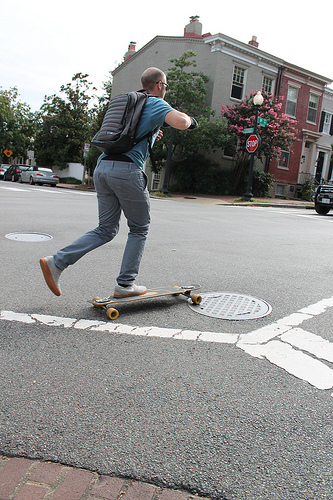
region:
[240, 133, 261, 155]
red octagonal stop sign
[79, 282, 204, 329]
old style skate board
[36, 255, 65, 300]
gum soled white shoes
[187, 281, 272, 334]
metal sewer system cover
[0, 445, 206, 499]
red bricks next to road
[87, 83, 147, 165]
grey striped back pack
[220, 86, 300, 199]
tall tree covered in pink flowers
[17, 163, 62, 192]
parked silver car with a black roof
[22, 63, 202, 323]
man riding a skateboard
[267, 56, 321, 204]
tall red brick building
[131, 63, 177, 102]
Man has thinning hair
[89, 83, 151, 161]
The man is carrying a backpack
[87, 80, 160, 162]
The man's backpack is gray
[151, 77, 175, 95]
The man is wearing glasses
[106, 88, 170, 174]
Man is wearing a blue shirt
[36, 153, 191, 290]
The man is wearing denim pants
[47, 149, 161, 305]
The man's pants are blue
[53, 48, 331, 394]
The man is not in the crosswalk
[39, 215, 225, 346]
The man is on a skateboard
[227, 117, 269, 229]
There is a stop sign at the intersection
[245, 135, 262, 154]
Red and white stop sign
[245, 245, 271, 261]
Small part of black street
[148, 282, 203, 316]
Half of the man's skateboard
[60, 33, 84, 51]
A white overcast sky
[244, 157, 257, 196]
Black pole that connects to stop sign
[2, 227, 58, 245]
Gray sewage hole in the street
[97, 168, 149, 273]
Gray jeans of the skateboarder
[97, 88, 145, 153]
Gray and black backpack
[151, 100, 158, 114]
Small part of green shirt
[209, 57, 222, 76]
Top part of gray building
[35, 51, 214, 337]
a man riding a skateboard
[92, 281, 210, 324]
a skateboard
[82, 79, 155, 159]
a grey backpack on the man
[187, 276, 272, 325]
a manhole cover in the road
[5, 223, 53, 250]
a manhole cover in the road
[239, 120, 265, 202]
a stop sign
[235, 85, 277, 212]
a street light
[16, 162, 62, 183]
a parked silver car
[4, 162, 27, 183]
a parked black car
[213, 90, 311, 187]
a tree with pink flowers on it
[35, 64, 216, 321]
Man on a skateboard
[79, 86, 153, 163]
A grey backpack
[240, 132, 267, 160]
A red stop sign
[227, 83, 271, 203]
A sign pole with a light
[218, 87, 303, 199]
A pink flowering tree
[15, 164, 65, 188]
A silver car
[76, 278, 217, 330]
A skateboard with yellow wheels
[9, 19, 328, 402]
A man riding a skateboard on the street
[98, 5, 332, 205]
A apartment building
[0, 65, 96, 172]
A group of green leafed trees